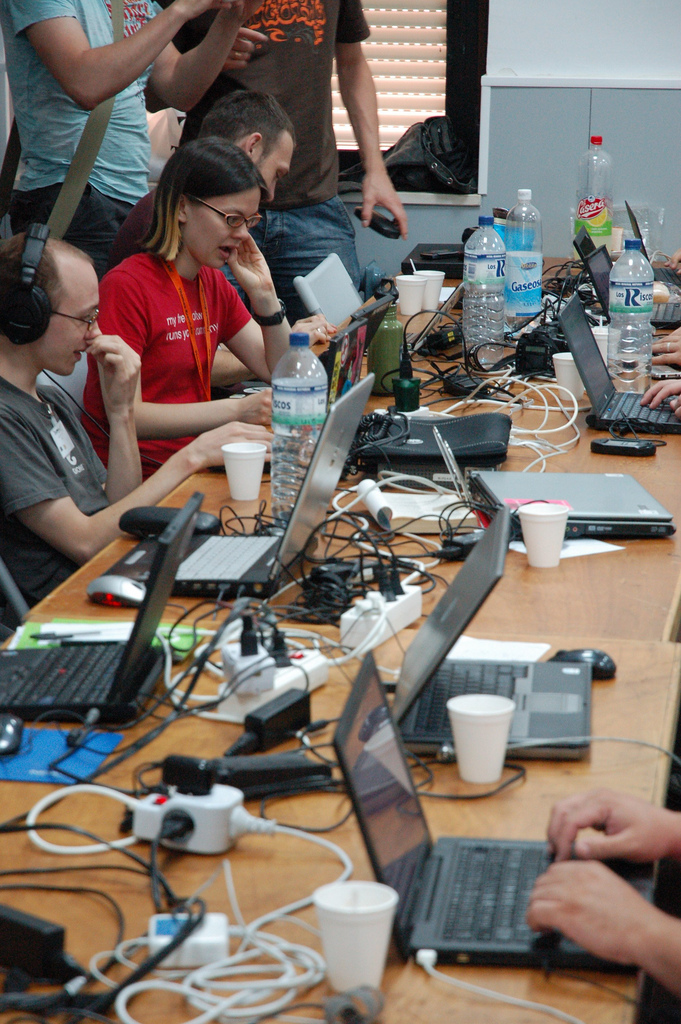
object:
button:
[458, 914, 470, 923]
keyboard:
[441, 840, 559, 938]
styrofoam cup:
[311, 877, 398, 995]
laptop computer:
[387, 504, 594, 768]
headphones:
[4, 225, 57, 343]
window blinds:
[324, 5, 443, 155]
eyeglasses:
[49, 307, 100, 329]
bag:
[337, 117, 476, 196]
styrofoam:
[444, 693, 514, 783]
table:
[2, 618, 680, 1021]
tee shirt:
[82, 247, 252, 480]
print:
[162, 307, 220, 342]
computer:
[329, 651, 655, 977]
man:
[530, 785, 678, 994]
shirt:
[146, 2, 370, 213]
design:
[245, 3, 325, 49]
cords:
[301, 514, 368, 549]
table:
[18, 255, 678, 643]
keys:
[461, 853, 520, 924]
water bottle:
[266, 332, 327, 532]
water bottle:
[460, 213, 503, 352]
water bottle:
[500, 183, 539, 334]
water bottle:
[605, 236, 650, 394]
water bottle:
[577, 128, 609, 259]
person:
[2, 230, 279, 601]